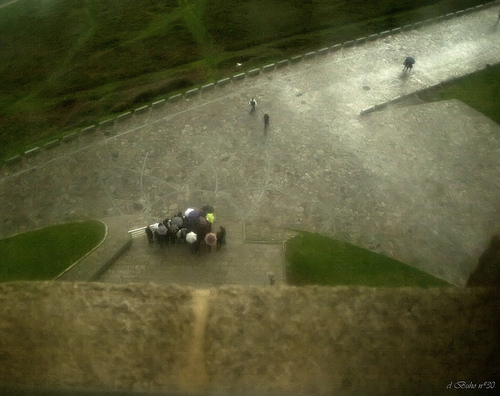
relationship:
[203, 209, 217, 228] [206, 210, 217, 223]
umbrella seen a part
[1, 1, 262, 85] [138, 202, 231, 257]
grass on left of people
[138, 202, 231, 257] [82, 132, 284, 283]
people standing on wet surface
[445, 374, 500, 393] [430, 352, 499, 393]
name in corner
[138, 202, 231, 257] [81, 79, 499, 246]
people on ground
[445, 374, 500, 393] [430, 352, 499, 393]
name in right corner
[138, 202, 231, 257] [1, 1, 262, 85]
people next to grass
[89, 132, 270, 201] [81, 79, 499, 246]
lines on ground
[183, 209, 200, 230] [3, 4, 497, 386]
umbrella in photo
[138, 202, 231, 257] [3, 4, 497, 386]
umbrellas in photo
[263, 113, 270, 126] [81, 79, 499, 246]
person on cement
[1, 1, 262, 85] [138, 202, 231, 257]
grass next to people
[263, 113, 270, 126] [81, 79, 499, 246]
person on ground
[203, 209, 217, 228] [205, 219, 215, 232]
umbrella covering person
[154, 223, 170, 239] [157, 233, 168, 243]
umbrella covering person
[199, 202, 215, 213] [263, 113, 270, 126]
umbrella covering a person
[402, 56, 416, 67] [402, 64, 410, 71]
umbrella covering a person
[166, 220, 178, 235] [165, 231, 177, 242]
umbrella covering a person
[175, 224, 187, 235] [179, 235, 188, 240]
umbrella covering a person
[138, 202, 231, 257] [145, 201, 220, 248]
people holding umbrellas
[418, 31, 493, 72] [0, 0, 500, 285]
light hitting floor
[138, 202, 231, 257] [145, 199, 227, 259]
umbrellas above people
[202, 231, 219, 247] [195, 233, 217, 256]
umbrella covering person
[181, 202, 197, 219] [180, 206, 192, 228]
umbrella covering person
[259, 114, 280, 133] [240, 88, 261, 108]
person walking with person